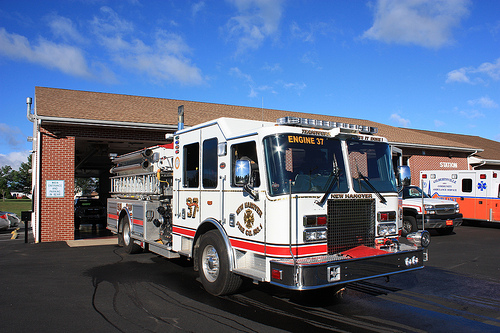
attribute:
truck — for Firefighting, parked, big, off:
[110, 112, 414, 301]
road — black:
[4, 208, 499, 331]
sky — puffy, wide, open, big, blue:
[1, 2, 499, 161]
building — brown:
[31, 84, 480, 261]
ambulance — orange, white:
[114, 124, 382, 285]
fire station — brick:
[42, 99, 460, 269]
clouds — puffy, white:
[36, 53, 260, 102]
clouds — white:
[14, 24, 241, 83]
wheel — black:
[103, 200, 147, 250]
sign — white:
[40, 180, 66, 209]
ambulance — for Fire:
[105, 101, 432, 297]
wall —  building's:
[42, 133, 74, 240]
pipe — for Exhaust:
[177, 99, 187, 131]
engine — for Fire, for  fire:
[105, 101, 421, 296]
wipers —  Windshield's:
[315, 171, 336, 204]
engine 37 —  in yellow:
[283, 133, 324, 146]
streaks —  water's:
[270, 294, 490, 330]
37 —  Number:
[179, 199, 198, 219]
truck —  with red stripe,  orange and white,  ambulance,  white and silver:
[105, 101, 426, 301]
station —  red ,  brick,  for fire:
[41, 82, 487, 248]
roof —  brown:
[38, 85, 482, 152]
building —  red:
[39, 141, 474, 241]